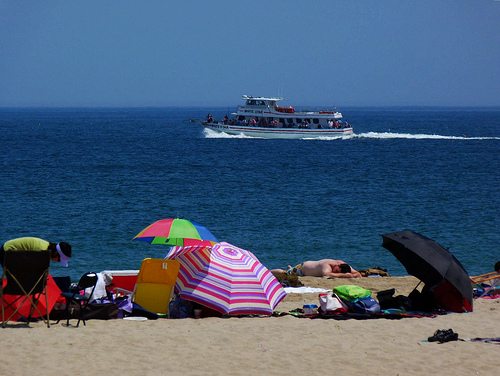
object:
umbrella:
[378, 228, 473, 313]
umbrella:
[162, 239, 287, 317]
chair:
[133, 257, 182, 314]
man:
[285, 258, 360, 279]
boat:
[189, 94, 353, 141]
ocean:
[152, 138, 263, 207]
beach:
[143, 311, 285, 375]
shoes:
[427, 327, 459, 344]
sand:
[308, 337, 355, 359]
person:
[0, 235, 72, 267]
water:
[74, 98, 129, 139]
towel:
[285, 285, 332, 294]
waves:
[363, 128, 413, 141]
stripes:
[215, 255, 237, 291]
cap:
[57, 245, 71, 268]